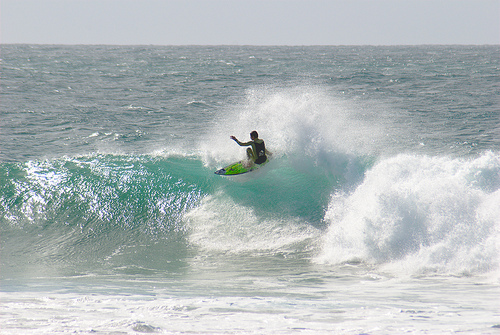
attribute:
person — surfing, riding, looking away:
[227, 128, 278, 173]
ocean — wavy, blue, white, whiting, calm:
[1, 40, 499, 334]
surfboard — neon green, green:
[213, 153, 275, 177]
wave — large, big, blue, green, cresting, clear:
[1, 145, 498, 254]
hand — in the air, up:
[229, 132, 237, 143]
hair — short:
[250, 129, 258, 140]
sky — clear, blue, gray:
[2, 1, 500, 49]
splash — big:
[211, 78, 381, 170]